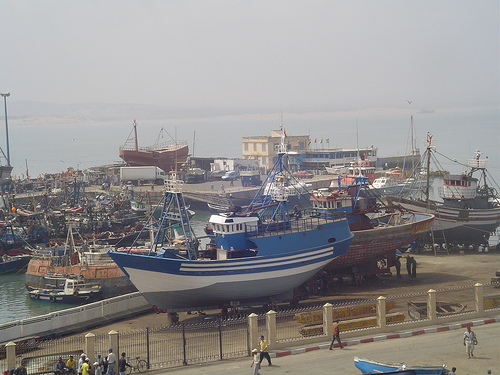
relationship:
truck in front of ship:
[119, 164, 171, 187] [119, 118, 193, 173]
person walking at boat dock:
[329, 320, 347, 353] [227, 314, 498, 374]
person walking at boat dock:
[254, 333, 271, 363] [227, 314, 498, 374]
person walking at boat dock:
[462, 322, 479, 359] [227, 314, 498, 374]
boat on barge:
[29, 279, 101, 300] [1, 190, 197, 274]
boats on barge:
[105, 171, 349, 303] [1, 190, 197, 274]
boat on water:
[29, 279, 101, 300] [0, 252, 100, 328]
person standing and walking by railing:
[254, 333, 271, 363] [107, 313, 248, 372]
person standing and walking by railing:
[462, 322, 479, 359] [107, 313, 248, 372]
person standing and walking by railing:
[329, 320, 347, 353] [107, 313, 248, 372]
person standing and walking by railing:
[113, 352, 132, 374] [107, 313, 248, 372]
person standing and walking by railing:
[103, 345, 118, 374] [107, 313, 248, 372]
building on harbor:
[227, 133, 332, 193] [67, 124, 497, 239]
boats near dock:
[105, 171, 349, 303] [146, 221, 404, 327]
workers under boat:
[395, 251, 418, 276] [340, 209, 447, 270]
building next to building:
[183, 133, 382, 193] [208, 155, 266, 176]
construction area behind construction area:
[0, 59, 499, 341] [2, 94, 494, 341]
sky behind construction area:
[3, 5, 498, 84] [2, 94, 494, 341]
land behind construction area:
[2, 92, 497, 124] [2, 94, 494, 341]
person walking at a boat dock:
[329, 320, 347, 353] [16, 136, 498, 356]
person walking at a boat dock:
[252, 346, 259, 373] [16, 136, 498, 356]